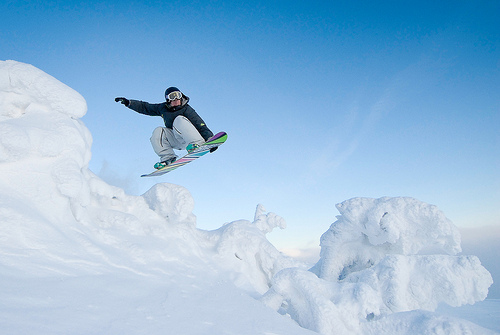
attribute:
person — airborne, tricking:
[115, 87, 227, 178]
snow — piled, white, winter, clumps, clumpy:
[0, 60, 499, 334]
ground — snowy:
[0, 213, 499, 334]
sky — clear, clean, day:
[1, 1, 499, 242]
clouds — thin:
[313, 71, 417, 179]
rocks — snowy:
[322, 200, 486, 321]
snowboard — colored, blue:
[140, 132, 230, 179]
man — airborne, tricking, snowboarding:
[115, 87, 219, 170]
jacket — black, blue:
[126, 93, 217, 143]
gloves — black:
[115, 95, 127, 104]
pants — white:
[151, 116, 206, 162]